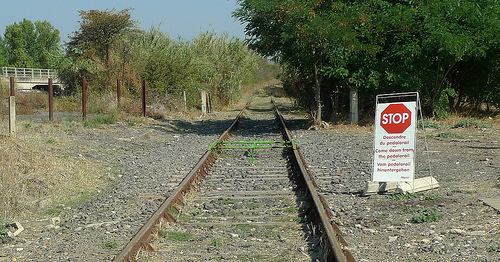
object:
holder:
[363, 92, 438, 196]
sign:
[373, 102, 416, 183]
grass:
[3, 102, 153, 235]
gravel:
[5, 109, 494, 259]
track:
[114, 93, 355, 261]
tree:
[235, 1, 420, 126]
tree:
[411, 0, 472, 123]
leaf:
[310, 22, 318, 31]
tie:
[195, 196, 300, 200]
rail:
[0, 67, 58, 78]